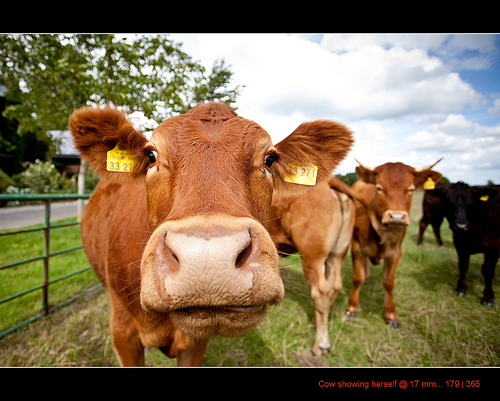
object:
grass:
[47, 310, 92, 355]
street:
[0, 192, 83, 229]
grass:
[0, 216, 75, 295]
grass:
[260, 235, 497, 368]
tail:
[331, 179, 401, 258]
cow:
[68, 100, 353, 371]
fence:
[0, 181, 120, 342]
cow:
[349, 158, 444, 328]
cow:
[270, 173, 399, 354]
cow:
[417, 181, 472, 246]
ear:
[67, 105, 148, 177]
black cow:
[447, 180, 500, 307]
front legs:
[383, 245, 403, 313]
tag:
[104, 143, 137, 172]